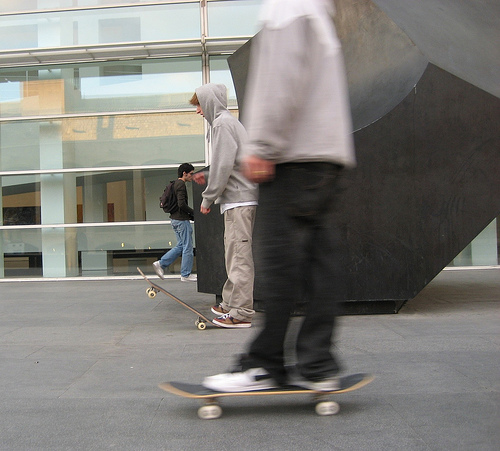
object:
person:
[202, 0, 349, 392]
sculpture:
[226, 1, 499, 312]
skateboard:
[134, 260, 216, 329]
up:
[136, 266, 195, 311]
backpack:
[159, 180, 179, 215]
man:
[153, 162, 196, 283]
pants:
[237, 159, 352, 382]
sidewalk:
[0, 274, 500, 449]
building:
[2, 0, 499, 275]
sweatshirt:
[197, 79, 262, 215]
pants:
[156, 216, 197, 280]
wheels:
[145, 287, 159, 299]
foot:
[210, 311, 255, 328]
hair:
[190, 92, 202, 107]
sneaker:
[202, 360, 287, 395]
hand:
[245, 153, 275, 184]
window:
[64, 109, 211, 169]